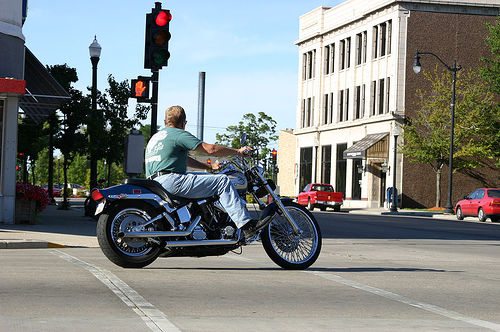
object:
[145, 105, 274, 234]
man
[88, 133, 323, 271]
motorcycle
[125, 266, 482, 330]
intersection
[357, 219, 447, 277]
street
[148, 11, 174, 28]
light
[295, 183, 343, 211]
truck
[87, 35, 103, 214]
post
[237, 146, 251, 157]
hand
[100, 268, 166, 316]
line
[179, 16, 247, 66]
sky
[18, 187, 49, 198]
bush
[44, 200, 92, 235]
sidewalk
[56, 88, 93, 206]
tree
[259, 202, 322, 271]
tire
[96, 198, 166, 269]
tire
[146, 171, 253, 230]
jeans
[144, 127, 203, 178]
shirt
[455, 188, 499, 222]
sedan